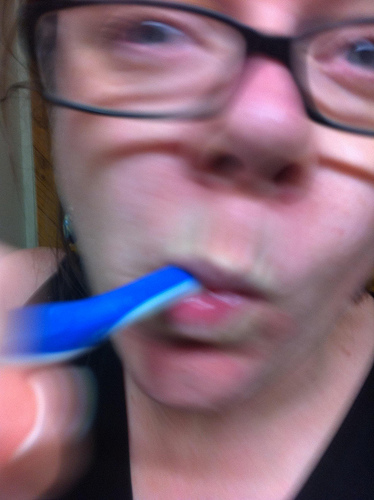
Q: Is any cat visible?
A: No, there are no cats.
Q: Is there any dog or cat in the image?
A: No, there are no cats or dogs.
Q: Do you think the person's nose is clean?
A: Yes, the nose is clean.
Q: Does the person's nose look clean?
A: Yes, the nose is clean.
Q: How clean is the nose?
A: The nose is clean.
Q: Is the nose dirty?
A: No, the nose is clean.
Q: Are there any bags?
A: No, there are no bags.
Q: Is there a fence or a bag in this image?
A: No, there are no bags or fences.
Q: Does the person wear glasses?
A: Yes, the person wears glasses.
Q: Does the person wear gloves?
A: No, the person wears glasses.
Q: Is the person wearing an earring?
A: Yes, the person is wearing an earring.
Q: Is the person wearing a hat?
A: No, the person is wearing an earring.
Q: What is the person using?
A: The person is using glasses.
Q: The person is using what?
A: The person is using glasses.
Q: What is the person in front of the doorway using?
A: The person is using glasses.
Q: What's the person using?
A: The person is using glasses.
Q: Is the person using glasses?
A: Yes, the person is using glasses.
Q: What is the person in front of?
A: The person is in front of the doorway.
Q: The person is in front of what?
A: The person is in front of the doorway.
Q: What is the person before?
A: The person is in front of the doorway.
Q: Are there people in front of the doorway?
A: Yes, there is a person in front of the doorway.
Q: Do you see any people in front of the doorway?
A: Yes, there is a person in front of the doorway.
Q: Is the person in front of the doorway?
A: Yes, the person is in front of the doorway.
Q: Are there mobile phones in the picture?
A: No, there are no mobile phones.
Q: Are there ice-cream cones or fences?
A: No, there are no fences or ice-cream cones.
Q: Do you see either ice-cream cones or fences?
A: No, there are no fences or ice-cream cones.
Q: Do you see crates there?
A: No, there are no crates.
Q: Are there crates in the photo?
A: No, there are no crates.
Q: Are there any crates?
A: No, there are no crates.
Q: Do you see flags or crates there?
A: No, there are no crates or flags.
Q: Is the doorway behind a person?
A: Yes, the doorway is behind a person.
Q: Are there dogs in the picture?
A: No, there are no dogs.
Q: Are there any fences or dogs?
A: No, there are no dogs or fences.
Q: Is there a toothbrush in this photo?
A: Yes, there is a toothbrush.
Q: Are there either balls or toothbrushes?
A: Yes, there is a toothbrush.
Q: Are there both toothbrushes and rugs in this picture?
A: No, there is a toothbrush but no rugs.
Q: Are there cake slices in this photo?
A: No, there are no cake slices.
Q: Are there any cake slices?
A: No, there are no cake slices.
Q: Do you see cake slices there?
A: No, there are no cake slices.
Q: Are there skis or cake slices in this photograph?
A: No, there are no cake slices or skis.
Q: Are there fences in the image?
A: No, there are no fences.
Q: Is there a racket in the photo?
A: No, there are no rackets.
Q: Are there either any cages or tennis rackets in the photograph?
A: No, there are no tennis rackets or cages.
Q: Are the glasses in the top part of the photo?
A: Yes, the glasses are in the top of the image.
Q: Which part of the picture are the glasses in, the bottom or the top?
A: The glasses are in the top of the image.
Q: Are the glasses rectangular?
A: Yes, the glasses are rectangular.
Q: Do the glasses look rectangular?
A: Yes, the glasses are rectangular.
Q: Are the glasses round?
A: No, the glasses are rectangular.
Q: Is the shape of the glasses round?
A: No, the glasses are rectangular.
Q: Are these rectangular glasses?
A: Yes, these are rectangular glasses.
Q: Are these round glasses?
A: No, these are rectangular glasses.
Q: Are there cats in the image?
A: No, there are no cats.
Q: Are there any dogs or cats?
A: No, there are no cats or dogs.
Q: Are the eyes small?
A: Yes, the eyes are small.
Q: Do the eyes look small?
A: Yes, the eyes are small.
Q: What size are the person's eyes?
A: The eyes are small.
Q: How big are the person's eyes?
A: The eyes are small.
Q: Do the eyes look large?
A: No, the eyes are small.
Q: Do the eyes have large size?
A: No, the eyes are small.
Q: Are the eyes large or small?
A: The eyes are small.